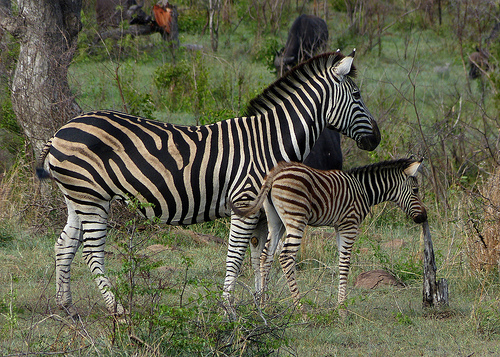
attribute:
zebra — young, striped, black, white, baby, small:
[227, 154, 428, 324]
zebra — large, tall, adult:
[35, 47, 381, 323]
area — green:
[1, 0, 500, 356]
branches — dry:
[0, 0, 500, 356]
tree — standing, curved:
[1, 0, 159, 235]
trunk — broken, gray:
[149, 2, 181, 53]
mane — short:
[352, 157, 416, 175]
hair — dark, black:
[226, 196, 247, 220]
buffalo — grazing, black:
[274, 15, 329, 78]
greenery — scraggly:
[1, 0, 500, 356]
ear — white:
[336, 46, 357, 76]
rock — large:
[353, 267, 406, 293]